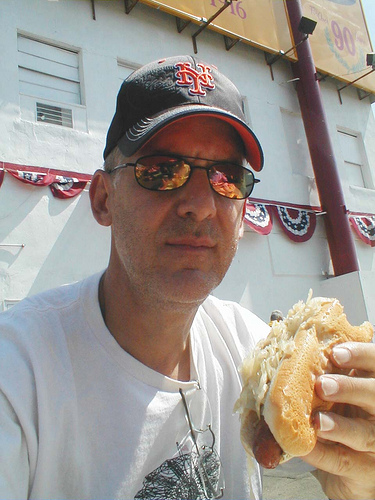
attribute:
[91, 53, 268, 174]
cap — red , black 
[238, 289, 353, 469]
bun — hot dog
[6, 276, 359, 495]
shirt — white cotton tee 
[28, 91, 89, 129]
conditioner — air 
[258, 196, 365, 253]
banner — hanging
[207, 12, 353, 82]
billboard — yellow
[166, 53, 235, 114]
logo — mets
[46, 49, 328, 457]
man — wearing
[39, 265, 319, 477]
shirt — white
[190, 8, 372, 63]
billboard — above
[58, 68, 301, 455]
man — holding, eating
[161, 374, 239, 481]
eyeglasses — hooked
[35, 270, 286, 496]
shirt — collared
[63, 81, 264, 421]
man — preparing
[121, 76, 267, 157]
cap — baseball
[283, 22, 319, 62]
lights — mounted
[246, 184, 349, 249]
flags — draped